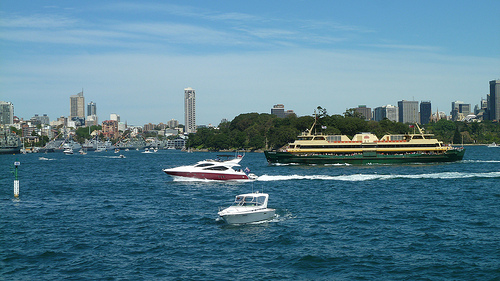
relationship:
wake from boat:
[253, 169, 498, 180] [162, 150, 256, 182]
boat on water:
[263, 121, 466, 164] [2, 148, 484, 278]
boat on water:
[217, 182, 275, 224] [2, 148, 484, 278]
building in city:
[181, 87, 196, 131] [3, 86, 205, 151]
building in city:
[69, 90, 85, 116] [3, 86, 205, 151]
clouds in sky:
[1, 0, 499, 129] [1, 0, 499, 128]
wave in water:
[181, 172, 498, 178] [2, 148, 484, 278]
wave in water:
[172, 172, 500, 182] [2, 148, 484, 278]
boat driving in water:
[204, 178, 285, 240] [302, 191, 422, 239]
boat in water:
[157, 152, 249, 191] [326, 151, 477, 240]